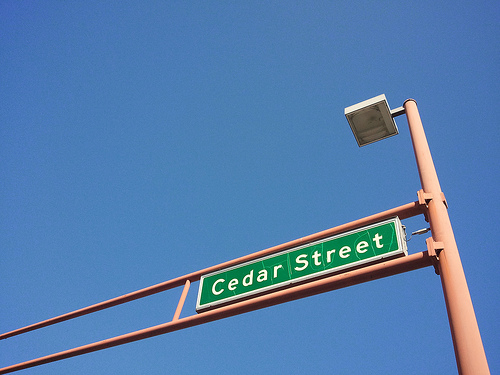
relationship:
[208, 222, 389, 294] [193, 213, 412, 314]
cedar street on sign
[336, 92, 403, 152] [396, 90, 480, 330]
light on post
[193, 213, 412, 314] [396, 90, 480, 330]
sign on pole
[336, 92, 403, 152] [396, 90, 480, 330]
light on pole